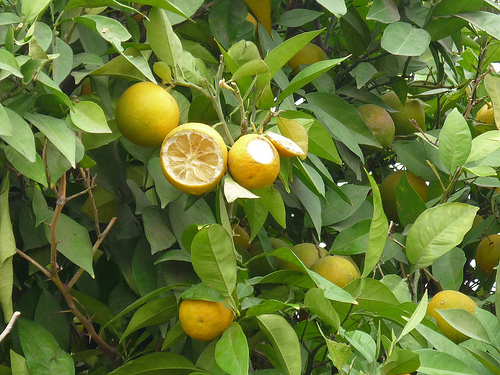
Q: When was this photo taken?
A: Daytime.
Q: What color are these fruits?
A: Yellow.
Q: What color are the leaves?
A: Green.